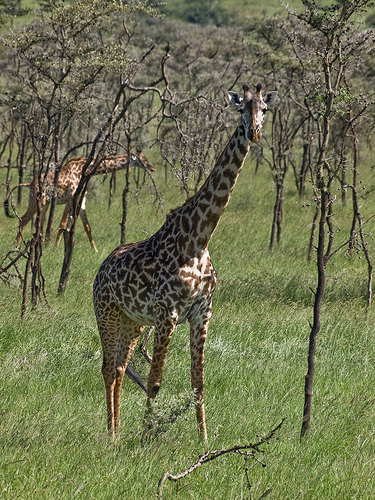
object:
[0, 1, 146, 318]
tall tree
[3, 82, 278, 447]
giraffes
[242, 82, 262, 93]
horns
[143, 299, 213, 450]
front legs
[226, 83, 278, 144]
head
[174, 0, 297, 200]
tree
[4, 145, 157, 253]
giraffe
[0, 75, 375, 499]
grass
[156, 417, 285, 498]
branch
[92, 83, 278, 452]
giraffe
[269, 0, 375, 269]
thin trees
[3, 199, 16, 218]
hair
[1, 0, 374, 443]
trees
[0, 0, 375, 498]
field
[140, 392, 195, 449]
bush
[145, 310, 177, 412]
giraffe's leg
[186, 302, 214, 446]
giraffe's leg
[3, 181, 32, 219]
tail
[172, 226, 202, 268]
spots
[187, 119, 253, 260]
neck